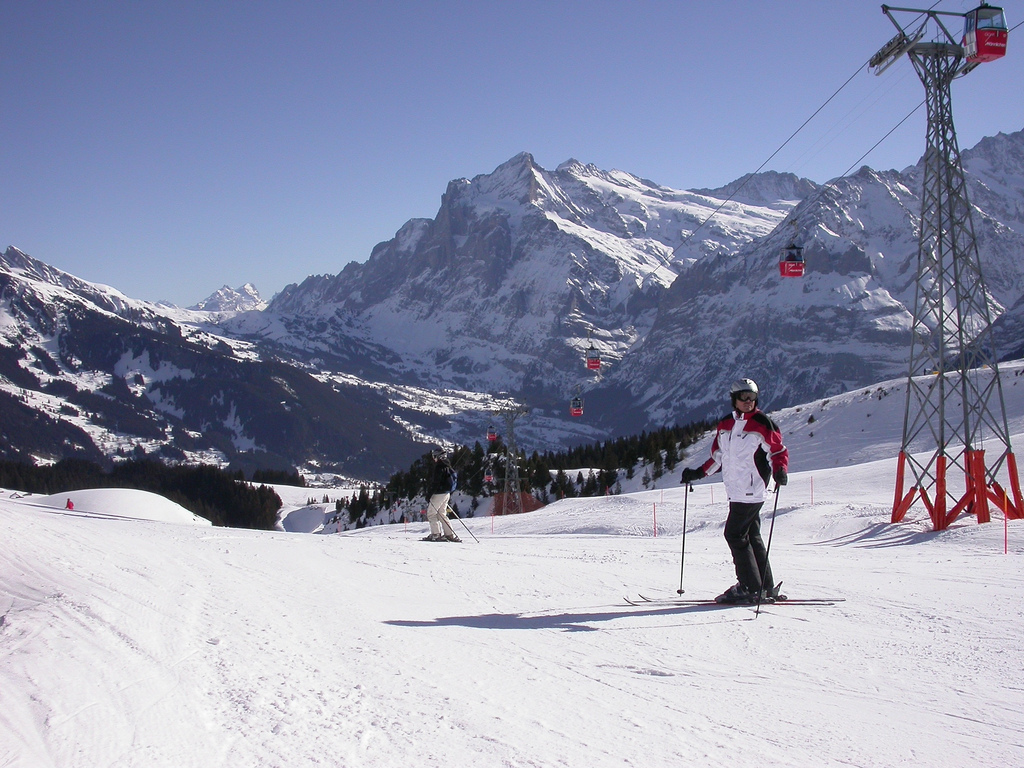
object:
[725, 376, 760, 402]
helmet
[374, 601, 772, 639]
shadow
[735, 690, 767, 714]
ground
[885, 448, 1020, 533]
paint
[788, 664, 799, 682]
snow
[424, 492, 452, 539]
trousers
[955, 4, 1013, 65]
lift cab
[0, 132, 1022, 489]
mountain range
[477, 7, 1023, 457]
cable lines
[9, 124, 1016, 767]
mountain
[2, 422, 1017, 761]
surface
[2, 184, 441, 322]
mountain gap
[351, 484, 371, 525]
trees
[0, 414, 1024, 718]
ski run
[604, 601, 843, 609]
skis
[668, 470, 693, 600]
ski pole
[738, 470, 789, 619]
ski pole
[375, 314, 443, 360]
snow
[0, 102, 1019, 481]
mountain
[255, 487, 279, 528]
tree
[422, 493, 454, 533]
pants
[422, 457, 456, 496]
jacket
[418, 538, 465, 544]
skis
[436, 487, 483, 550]
ski pole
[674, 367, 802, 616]
person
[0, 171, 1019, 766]
ski area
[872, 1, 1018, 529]
tower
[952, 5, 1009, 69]
gondola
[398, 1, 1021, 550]
ski lift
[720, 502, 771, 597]
pants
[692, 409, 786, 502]
parka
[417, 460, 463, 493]
parka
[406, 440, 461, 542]
skier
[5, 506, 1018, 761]
snow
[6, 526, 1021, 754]
ski tracks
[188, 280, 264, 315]
mountain peak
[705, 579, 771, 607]
boots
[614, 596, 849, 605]
skis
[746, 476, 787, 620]
pole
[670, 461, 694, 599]
pole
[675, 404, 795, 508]
jacket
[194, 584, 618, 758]
snow